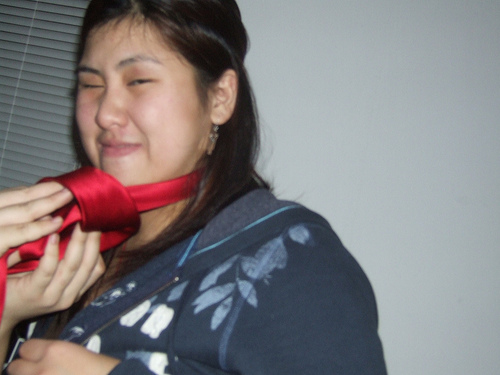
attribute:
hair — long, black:
[71, 3, 258, 213]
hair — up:
[43, 0, 272, 332]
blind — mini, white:
[0, 1, 87, 192]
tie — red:
[12, 165, 217, 265]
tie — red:
[55, 161, 250, 276]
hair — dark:
[74, 1, 271, 290]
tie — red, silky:
[0, 163, 232, 316]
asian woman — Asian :
[0, 1, 390, 373]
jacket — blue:
[145, 196, 362, 338]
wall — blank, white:
[266, 0, 496, 246]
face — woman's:
[67, 51, 182, 181]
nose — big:
[88, 86, 129, 131]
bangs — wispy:
[83, 9, 163, 35]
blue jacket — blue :
[0, 187, 388, 373]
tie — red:
[0, 167, 211, 322]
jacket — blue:
[15, 185, 388, 374]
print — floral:
[190, 215, 313, 332]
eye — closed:
[77, 75, 104, 92]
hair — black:
[192, 10, 237, 65]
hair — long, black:
[72, 0, 264, 313]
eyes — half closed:
[78, 76, 156, 88]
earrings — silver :
[202, 119, 226, 147]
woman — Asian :
[20, 6, 363, 369]